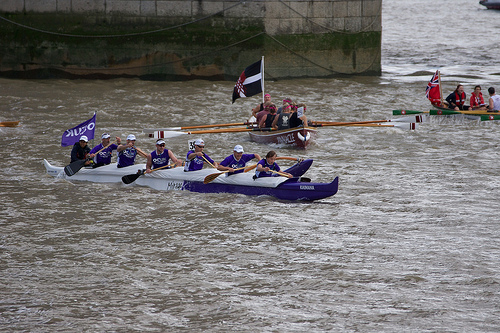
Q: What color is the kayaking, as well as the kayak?
A: Purple and white.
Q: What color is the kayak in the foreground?
A: Blue and white.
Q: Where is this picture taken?
A: A river.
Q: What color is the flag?
A: Red, black and white.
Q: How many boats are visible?
A: Three.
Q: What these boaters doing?
A: Competing.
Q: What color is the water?
A: Grey.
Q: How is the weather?
A: Overcast.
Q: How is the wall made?
A: Of concrete.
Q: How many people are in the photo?
A: Seventeen.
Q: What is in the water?
A: Boats.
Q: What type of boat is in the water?
A: Kayak.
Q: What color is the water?
A: Blue and white.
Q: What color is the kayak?
A: Blue and white.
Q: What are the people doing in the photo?
A: Kayaking.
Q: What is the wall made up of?
A: Cement.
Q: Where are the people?
A: A boat.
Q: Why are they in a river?
A: Racing.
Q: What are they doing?
A: Speed racing.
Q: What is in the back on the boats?
A: Flags.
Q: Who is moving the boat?
A: A group of people.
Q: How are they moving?
A: Using paddles.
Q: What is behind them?
A: A cement block.